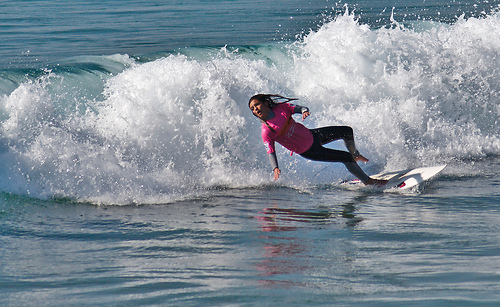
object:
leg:
[314, 126, 360, 156]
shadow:
[256, 184, 382, 283]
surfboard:
[329, 164, 448, 192]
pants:
[298, 126, 370, 185]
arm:
[261, 133, 279, 172]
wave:
[0, 0, 500, 208]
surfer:
[246, 94, 388, 188]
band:
[268, 152, 278, 171]